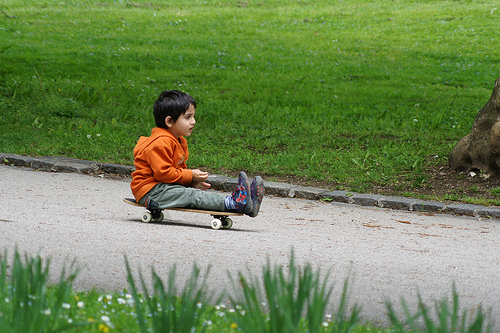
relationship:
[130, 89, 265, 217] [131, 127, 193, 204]
boy wearing hoodie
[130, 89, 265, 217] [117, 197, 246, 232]
boy on skateboard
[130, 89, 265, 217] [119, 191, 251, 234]
boy sitting on skateboard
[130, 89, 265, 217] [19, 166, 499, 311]
boy skateboarding on path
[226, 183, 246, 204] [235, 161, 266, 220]
shoelaces are attached to sneakers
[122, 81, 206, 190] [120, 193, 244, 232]
boy sitting on skateboard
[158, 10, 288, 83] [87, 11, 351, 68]
flowers are growing in grass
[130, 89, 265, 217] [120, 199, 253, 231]
boy sitting on skateboard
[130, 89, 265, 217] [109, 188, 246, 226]
boy sitting on skateboard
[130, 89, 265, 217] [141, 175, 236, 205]
boy wearing pants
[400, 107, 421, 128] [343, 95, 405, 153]
flower growing in grass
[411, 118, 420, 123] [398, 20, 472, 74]
flower are growing in grass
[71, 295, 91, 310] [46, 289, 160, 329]
flower growing in grass